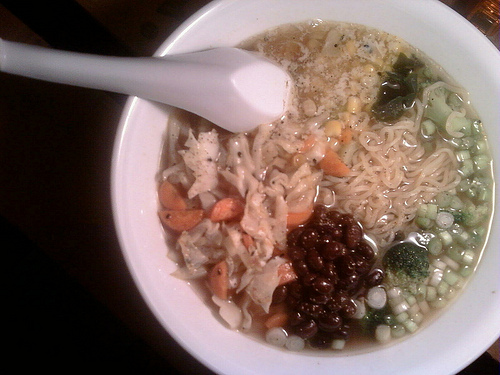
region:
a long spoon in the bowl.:
[108, 37, 301, 134]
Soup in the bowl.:
[213, 94, 459, 291]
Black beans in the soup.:
[299, 224, 358, 309]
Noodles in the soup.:
[338, 117, 423, 232]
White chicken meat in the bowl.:
[204, 148, 296, 300]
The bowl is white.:
[107, 132, 174, 302]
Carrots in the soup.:
[158, 156, 245, 238]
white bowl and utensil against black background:
[5, 8, 497, 368]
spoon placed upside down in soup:
[5, 18, 295, 140]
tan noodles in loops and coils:
[326, 117, 460, 234]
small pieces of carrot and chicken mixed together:
[166, 116, 311, 317]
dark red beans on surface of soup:
[276, 203, 384, 348]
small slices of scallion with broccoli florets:
[376, 84, 492, 339]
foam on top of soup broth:
[253, 19, 392, 119]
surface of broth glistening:
[381, 88, 491, 327]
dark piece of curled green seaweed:
[368, 47, 428, 127]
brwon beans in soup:
[289, 212, 391, 341]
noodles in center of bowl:
[332, 128, 450, 245]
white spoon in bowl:
[2, 26, 301, 128]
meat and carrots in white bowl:
[172, 128, 297, 340]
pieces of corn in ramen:
[326, 91, 363, 133]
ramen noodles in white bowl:
[332, 100, 458, 240]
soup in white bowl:
[115, 9, 498, 374]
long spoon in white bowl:
[5, 34, 318, 131]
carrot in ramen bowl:
[309, 133, 349, 183]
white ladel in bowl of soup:
[3, 40, 295, 142]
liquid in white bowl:
[356, 228, 422, 256]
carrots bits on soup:
[157, 177, 206, 238]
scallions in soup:
[437, 215, 477, 251]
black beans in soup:
[283, 198, 380, 342]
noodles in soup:
[352, 132, 404, 197]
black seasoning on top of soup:
[200, 154, 218, 164]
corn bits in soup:
[320, 89, 365, 141]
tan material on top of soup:
[288, 44, 322, 94]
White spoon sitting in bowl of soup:
[2, 38, 295, 134]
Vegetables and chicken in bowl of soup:
[158, 122, 348, 329]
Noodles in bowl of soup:
[327, 99, 461, 245]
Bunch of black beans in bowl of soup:
[286, 207, 382, 347]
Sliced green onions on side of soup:
[366, 115, 489, 343]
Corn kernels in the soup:
[321, 95, 361, 137]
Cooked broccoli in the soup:
[377, 241, 433, 278]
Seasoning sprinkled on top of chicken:
[181, 132, 225, 194]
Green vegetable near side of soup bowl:
[367, 52, 424, 124]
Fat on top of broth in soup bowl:
[263, 22, 382, 111]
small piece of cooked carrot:
[158, 208, 205, 230]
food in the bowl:
[130, 37, 495, 342]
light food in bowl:
[178, 123, 316, 265]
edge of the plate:
[77, 108, 164, 286]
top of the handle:
[183, 33, 297, 135]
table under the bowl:
[23, 9, 155, 51]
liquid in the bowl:
[268, 25, 380, 120]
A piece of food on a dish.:
[371, 282, 389, 316]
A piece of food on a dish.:
[292, 211, 359, 369]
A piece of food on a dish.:
[216, 194, 255, 221]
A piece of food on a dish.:
[162, 204, 220, 244]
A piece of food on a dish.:
[162, 183, 183, 209]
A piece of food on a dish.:
[213, 256, 223, 285]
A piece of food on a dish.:
[175, 132, 292, 321]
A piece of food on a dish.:
[316, 81, 439, 238]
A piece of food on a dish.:
[423, 92, 485, 305]